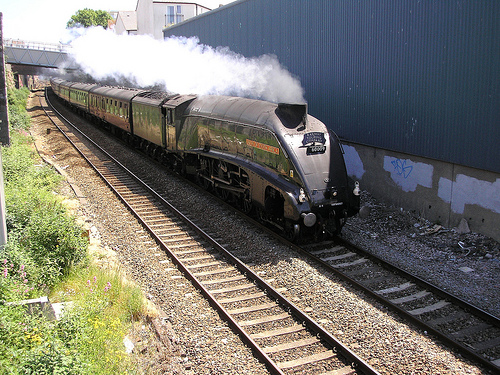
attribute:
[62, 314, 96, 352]
patch — small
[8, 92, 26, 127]
grass — green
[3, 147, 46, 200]
grass — green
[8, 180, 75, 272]
grass — green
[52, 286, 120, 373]
grass — green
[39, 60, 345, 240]
engine — long, steam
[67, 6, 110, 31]
tree — green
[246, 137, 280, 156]
label — orange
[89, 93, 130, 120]
windows — bunch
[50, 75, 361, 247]
train — gray, black, left side, large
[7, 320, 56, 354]
grass — green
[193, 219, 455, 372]
tracks — gray, metal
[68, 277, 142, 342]
grass — green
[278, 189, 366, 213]
front light — small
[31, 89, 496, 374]
gravel — gray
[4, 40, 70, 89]
bridge — gray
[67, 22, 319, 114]
smoke — white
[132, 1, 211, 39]
building — white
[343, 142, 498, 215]
patches — white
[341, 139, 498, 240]
cement fundation — gray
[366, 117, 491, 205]
brick wall — gray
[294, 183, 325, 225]
light — little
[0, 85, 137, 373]
grass — green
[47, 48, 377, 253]
train — black, large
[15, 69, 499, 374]
tracks — train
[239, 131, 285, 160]
label — orange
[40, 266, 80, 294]
grass — green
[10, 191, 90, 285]
shrubs — green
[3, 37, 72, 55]
rails — gray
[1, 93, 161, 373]
grass — green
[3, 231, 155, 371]
patch — small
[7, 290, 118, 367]
patch — small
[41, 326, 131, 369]
patch — small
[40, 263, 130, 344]
patch — small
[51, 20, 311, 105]
cloud — big, white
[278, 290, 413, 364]
gravel — gray